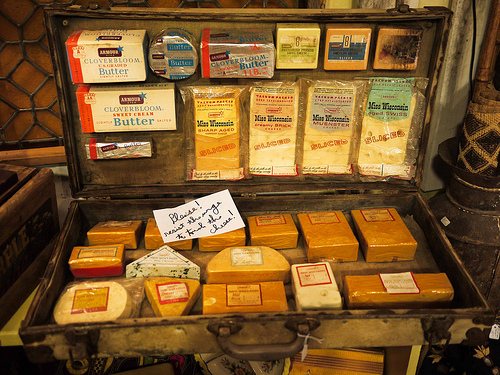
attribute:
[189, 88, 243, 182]
cheese — sharp, aged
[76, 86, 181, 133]
butter stick — white, one pound, packaged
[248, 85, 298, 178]
swiss cheese — aged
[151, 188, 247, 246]
note — small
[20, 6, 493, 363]
luggage — full, full of cheese, battered, filled with cheese, filled with butter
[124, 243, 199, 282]
cheese — triangular, spotted, white, green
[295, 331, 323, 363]
tag — white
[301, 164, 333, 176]
sticker — red, white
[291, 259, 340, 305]
cheese — white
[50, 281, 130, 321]
cheese — circular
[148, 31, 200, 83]
butter block — round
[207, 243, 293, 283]
cheese — a half moon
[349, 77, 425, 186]
bag — clear, labeled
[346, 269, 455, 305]
cheese brick — yellow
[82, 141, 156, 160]
package — silver